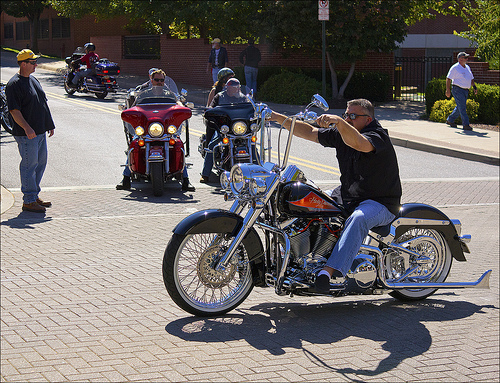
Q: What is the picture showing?
A: It is showing a road.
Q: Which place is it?
A: It is a road.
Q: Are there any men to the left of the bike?
A: Yes, there is a man to the left of the bike.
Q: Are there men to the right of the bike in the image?
A: No, the man is to the left of the bike.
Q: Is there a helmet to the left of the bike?
A: No, there is a man to the left of the bike.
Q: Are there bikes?
A: Yes, there is a bike.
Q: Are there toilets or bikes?
A: Yes, there is a bike.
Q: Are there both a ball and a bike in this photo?
A: No, there is a bike but no balls.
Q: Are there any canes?
A: No, there are no canes.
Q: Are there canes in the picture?
A: No, there are no canes.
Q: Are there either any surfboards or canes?
A: No, there are no canes or surfboards.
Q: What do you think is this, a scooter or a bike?
A: This is a bike.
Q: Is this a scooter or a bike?
A: This is a bike.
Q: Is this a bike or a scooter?
A: This is a bike.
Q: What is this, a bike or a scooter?
A: This is a bike.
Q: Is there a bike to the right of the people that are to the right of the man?
A: Yes, there is a bike to the right of the people.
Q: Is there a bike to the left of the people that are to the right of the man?
A: No, the bike is to the right of the people.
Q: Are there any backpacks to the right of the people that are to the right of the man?
A: No, there is a bike to the right of the people.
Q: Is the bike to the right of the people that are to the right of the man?
A: Yes, the bike is to the right of the people.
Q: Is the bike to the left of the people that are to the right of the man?
A: No, the bike is to the right of the people.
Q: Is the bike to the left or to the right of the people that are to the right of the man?
A: The bike is to the right of the people.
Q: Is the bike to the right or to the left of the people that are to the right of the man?
A: The bike is to the right of the people.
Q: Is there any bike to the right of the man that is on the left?
A: Yes, there is a bike to the right of the man.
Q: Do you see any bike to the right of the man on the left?
A: Yes, there is a bike to the right of the man.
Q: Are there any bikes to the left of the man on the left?
A: No, the bike is to the right of the man.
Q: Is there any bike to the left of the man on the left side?
A: No, the bike is to the right of the man.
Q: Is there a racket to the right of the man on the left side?
A: No, there is a bike to the right of the man.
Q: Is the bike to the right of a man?
A: Yes, the bike is to the right of a man.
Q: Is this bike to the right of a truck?
A: No, the bike is to the right of a man.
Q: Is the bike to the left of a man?
A: No, the bike is to the right of a man.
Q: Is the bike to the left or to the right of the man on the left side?
A: The bike is to the right of the man.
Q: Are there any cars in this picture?
A: No, there are no cars.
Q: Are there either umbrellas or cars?
A: No, there are no cars or umbrellas.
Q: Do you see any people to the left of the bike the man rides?
A: Yes, there are people to the left of the bike.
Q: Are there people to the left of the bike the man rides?
A: Yes, there are people to the left of the bike.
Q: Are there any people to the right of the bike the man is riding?
A: No, the people are to the left of the bike.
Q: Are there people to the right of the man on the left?
A: Yes, there are people to the right of the man.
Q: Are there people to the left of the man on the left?
A: No, the people are to the right of the man.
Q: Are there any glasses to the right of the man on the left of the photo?
A: No, there are people to the right of the man.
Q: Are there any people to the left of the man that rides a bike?
A: Yes, there are people to the left of the man.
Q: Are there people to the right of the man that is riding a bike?
A: No, the people are to the left of the man.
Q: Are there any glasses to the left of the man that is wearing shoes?
A: No, there are people to the left of the man.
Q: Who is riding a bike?
A: The man is riding a bike.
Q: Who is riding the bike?
A: The man is riding a bike.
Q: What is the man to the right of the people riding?
A: The man is riding a bike.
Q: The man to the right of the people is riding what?
A: The man is riding a bike.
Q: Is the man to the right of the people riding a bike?
A: Yes, the man is riding a bike.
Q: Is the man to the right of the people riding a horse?
A: No, the man is riding a bike.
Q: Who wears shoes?
A: The man wears shoes.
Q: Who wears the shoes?
A: The man wears shoes.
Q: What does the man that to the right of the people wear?
A: The man wears shoes.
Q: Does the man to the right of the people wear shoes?
A: Yes, the man wears shoes.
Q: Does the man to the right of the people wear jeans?
A: No, the man wears shoes.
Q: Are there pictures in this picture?
A: No, there are no pictures.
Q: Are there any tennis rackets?
A: No, there are no tennis rackets.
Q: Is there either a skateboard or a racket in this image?
A: No, there are no rackets or skateboards.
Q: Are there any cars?
A: No, there are no cars.